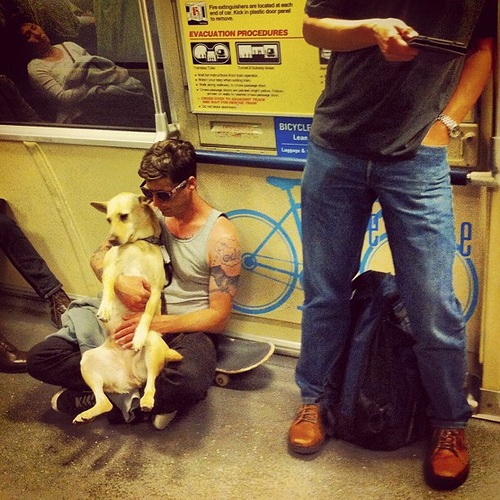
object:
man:
[28, 132, 257, 432]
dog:
[72, 186, 188, 430]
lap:
[166, 362, 209, 417]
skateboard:
[214, 331, 277, 389]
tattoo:
[207, 238, 246, 304]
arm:
[161, 217, 243, 335]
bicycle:
[210, 171, 487, 346]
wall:
[5, 2, 497, 421]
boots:
[285, 396, 329, 458]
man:
[262, 0, 495, 490]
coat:
[42, 293, 109, 355]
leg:
[23, 293, 182, 434]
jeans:
[24, 325, 221, 426]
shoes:
[132, 391, 180, 432]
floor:
[4, 295, 499, 498]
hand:
[421, 119, 464, 143]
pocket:
[410, 144, 448, 182]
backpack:
[325, 269, 430, 453]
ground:
[5, 289, 500, 492]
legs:
[382, 143, 476, 493]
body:
[22, 198, 242, 429]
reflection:
[9, 17, 135, 116]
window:
[5, 0, 177, 142]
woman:
[15, 13, 152, 116]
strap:
[61, 40, 78, 67]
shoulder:
[50, 39, 80, 59]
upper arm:
[209, 228, 244, 312]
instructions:
[179, 4, 303, 112]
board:
[177, 0, 335, 121]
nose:
[109, 231, 118, 246]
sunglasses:
[136, 177, 188, 203]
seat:
[211, 333, 276, 377]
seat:
[5, 6, 64, 120]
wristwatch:
[438, 107, 465, 141]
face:
[450, 123, 465, 139]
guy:
[21, 134, 246, 432]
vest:
[135, 204, 227, 323]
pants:
[0, 193, 66, 303]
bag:
[328, 268, 448, 454]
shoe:
[422, 429, 478, 493]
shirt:
[27, 36, 96, 110]